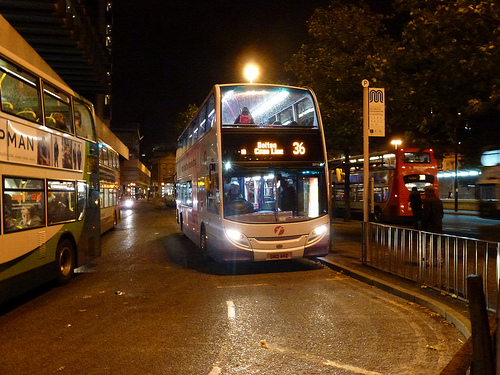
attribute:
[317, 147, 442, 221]
bus —  red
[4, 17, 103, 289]
bus — green,  filled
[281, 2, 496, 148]
trees — green, Leafy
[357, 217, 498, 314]
railing — silver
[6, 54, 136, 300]
bus — double decker, green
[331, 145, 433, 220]
bus — red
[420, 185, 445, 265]
people — walking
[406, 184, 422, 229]
people — walking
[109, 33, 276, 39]
sky — dark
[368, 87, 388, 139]
sign — hanging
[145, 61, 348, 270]
bus —  white, double decker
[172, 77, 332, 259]
bus — double decker